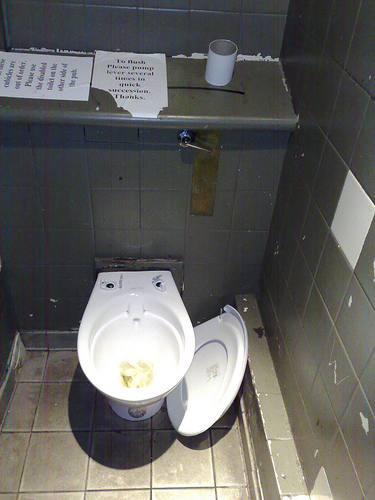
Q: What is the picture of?
A: A toilet.